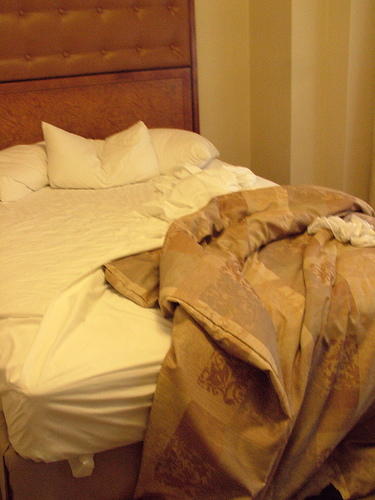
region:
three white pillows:
[0, 108, 212, 195]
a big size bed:
[0, 113, 169, 458]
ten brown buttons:
[5, 2, 185, 63]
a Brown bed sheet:
[144, 183, 371, 490]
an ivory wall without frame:
[232, 16, 362, 174]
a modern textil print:
[196, 349, 262, 410]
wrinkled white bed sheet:
[0, 232, 137, 472]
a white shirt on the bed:
[139, 140, 259, 215]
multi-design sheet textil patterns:
[180, 229, 347, 485]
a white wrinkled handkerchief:
[308, 210, 371, 247]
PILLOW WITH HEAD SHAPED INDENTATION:
[24, 109, 167, 190]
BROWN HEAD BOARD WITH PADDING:
[4, 1, 207, 143]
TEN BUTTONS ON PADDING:
[6, 7, 190, 69]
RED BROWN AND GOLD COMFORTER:
[97, 186, 370, 495]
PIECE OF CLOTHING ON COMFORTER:
[290, 199, 374, 271]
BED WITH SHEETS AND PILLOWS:
[8, 130, 369, 487]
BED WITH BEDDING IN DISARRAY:
[3, 118, 372, 472]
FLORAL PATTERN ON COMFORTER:
[195, 339, 273, 424]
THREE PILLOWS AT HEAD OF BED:
[5, 113, 221, 207]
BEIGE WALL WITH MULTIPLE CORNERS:
[179, 2, 371, 186]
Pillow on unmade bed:
[39, 118, 163, 187]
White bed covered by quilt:
[0, 147, 264, 404]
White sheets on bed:
[30, 197, 128, 291]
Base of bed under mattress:
[5, 452, 149, 488]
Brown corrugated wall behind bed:
[196, 28, 373, 196]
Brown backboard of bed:
[0, 10, 199, 127]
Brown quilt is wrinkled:
[119, 243, 372, 485]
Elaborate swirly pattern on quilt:
[196, 354, 279, 418]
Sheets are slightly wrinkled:
[23, 285, 153, 431]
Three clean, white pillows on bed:
[1, 109, 222, 192]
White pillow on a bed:
[40, 120, 160, 188]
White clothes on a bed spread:
[304, 203, 373, 244]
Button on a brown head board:
[130, 4, 141, 13]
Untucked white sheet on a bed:
[65, 452, 98, 477]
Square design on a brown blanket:
[154, 399, 270, 498]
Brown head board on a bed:
[0, 1, 197, 139]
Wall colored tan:
[194, 0, 254, 176]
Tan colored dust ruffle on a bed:
[4, 447, 137, 498]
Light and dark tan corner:
[247, 0, 320, 195]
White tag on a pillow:
[184, 165, 209, 178]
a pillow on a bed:
[38, 117, 160, 186]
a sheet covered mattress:
[1, 155, 287, 463]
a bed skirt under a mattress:
[1, 413, 146, 498]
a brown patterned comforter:
[102, 181, 372, 498]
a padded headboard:
[0, 1, 201, 148]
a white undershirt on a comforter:
[308, 208, 374, 251]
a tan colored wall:
[195, 0, 373, 201]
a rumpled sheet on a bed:
[142, 159, 258, 229]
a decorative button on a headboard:
[99, 48, 108, 55]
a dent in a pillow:
[78, 134, 123, 178]